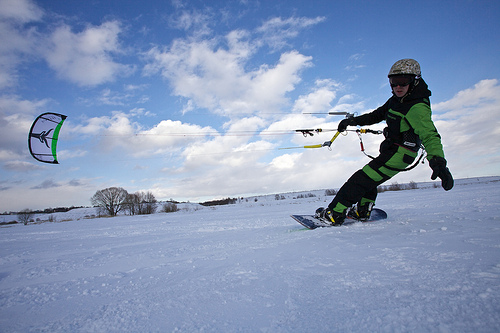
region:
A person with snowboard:
[281, 39, 470, 252]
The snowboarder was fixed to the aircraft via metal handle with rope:
[21, 96, 380, 153]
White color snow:
[110, 246, 231, 302]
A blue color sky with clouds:
[108, 45, 304, 90]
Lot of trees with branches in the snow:
[20, 177, 217, 237]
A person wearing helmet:
[385, 53, 436, 98]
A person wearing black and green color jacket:
[367, 100, 452, 147]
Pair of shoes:
[317, 202, 377, 229]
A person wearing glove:
[430, 157, 456, 187]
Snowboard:
[286, 206, 316, 241]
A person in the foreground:
[268, 27, 472, 239]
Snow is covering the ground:
[0, 170, 499, 331]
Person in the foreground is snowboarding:
[282, 48, 478, 239]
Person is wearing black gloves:
[330, 83, 478, 198]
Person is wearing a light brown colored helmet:
[372, 56, 433, 93]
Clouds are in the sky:
[3, 0, 498, 185]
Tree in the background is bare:
[89, 181, 188, 219]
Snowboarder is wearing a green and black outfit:
[323, 85, 449, 225]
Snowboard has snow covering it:
[279, 192, 402, 240]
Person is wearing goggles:
[378, 48, 443, 109]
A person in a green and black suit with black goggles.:
[316, 59, 456, 226]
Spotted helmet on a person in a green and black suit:
[385, 57, 422, 87]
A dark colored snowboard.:
[288, 205, 385, 227]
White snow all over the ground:
[0, 188, 499, 330]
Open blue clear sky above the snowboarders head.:
[322, 2, 499, 59]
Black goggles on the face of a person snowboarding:
[387, 73, 422, 88]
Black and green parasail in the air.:
[28, 111, 68, 165]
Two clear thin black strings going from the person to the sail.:
[63, 126, 336, 136]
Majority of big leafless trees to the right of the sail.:
[92, 188, 155, 216]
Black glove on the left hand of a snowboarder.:
[428, 155, 453, 190]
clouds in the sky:
[141, 30, 273, 118]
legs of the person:
[328, 152, 413, 209]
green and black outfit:
[279, 73, 464, 251]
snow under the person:
[214, 237, 314, 307]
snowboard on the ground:
[272, 190, 397, 250]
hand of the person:
[420, 150, 461, 206]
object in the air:
[13, 95, 101, 182]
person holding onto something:
[245, 42, 474, 257]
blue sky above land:
[334, 6, 421, 48]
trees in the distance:
[73, 178, 173, 253]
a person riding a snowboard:
[272, 63, 464, 240]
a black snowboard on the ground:
[286, 202, 394, 236]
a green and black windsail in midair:
[13, 93, 74, 175]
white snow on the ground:
[241, 282, 401, 320]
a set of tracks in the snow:
[72, 210, 284, 247]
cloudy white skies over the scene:
[119, 45, 283, 167]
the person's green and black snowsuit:
[328, 103, 453, 242]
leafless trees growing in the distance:
[26, 183, 178, 220]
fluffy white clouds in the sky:
[191, 110, 336, 187]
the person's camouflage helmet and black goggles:
[381, 57, 426, 99]